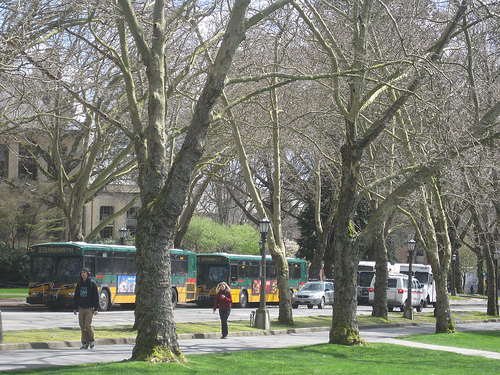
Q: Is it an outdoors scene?
A: Yes, it is outdoors.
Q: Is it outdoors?
A: Yes, it is outdoors.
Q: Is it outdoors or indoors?
A: It is outdoors.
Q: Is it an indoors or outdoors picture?
A: It is outdoors.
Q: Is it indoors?
A: No, it is outdoors.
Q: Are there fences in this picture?
A: No, there are no fences.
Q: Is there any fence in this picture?
A: No, there are no fences.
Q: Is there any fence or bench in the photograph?
A: No, there are no fences or benches.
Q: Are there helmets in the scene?
A: No, there are no helmets.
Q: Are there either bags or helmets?
A: No, there are no helmets or bags.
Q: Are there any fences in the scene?
A: No, there are no fences.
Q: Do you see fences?
A: No, there are no fences.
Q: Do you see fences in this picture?
A: No, there are no fences.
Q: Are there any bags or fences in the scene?
A: No, there are no fences or bags.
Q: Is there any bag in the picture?
A: No, there are no bags.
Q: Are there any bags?
A: No, there are no bags.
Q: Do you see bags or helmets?
A: No, there are no bags or helmets.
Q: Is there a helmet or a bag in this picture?
A: No, there are no bags or helmets.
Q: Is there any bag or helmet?
A: No, there are no bags or helmets.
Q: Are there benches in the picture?
A: No, there are no benches.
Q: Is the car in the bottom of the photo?
A: Yes, the car is in the bottom of the image.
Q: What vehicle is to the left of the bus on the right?
A: The vehicle is a car.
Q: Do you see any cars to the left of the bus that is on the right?
A: Yes, there is a car to the left of the bus.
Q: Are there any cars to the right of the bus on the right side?
A: No, the car is to the left of the bus.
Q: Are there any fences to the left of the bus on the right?
A: No, there is a car to the left of the bus.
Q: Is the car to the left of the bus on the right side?
A: Yes, the car is to the left of the bus.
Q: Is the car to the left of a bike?
A: No, the car is to the left of the bus.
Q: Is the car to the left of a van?
A: Yes, the car is to the left of a van.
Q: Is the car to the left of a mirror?
A: No, the car is to the left of a van.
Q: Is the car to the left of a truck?
A: No, the car is to the left of a van.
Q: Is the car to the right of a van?
A: No, the car is to the left of a van.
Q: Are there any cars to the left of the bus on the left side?
A: No, the car is to the right of the bus.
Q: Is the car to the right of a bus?
A: Yes, the car is to the right of a bus.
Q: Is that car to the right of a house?
A: No, the car is to the right of a bus.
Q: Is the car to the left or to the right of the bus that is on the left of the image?
A: The car is to the right of the bus.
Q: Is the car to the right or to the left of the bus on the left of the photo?
A: The car is to the right of the bus.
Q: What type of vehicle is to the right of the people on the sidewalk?
A: The vehicle is a car.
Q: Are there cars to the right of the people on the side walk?
A: Yes, there is a car to the right of the people.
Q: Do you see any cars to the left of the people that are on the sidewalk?
A: No, the car is to the right of the people.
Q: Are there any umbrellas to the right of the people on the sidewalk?
A: No, there is a car to the right of the people.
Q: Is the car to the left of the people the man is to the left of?
A: No, the car is to the right of the people.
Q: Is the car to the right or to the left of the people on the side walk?
A: The car is to the right of the people.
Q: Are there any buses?
A: Yes, there is a bus.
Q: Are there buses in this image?
A: Yes, there is a bus.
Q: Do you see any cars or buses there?
A: Yes, there is a bus.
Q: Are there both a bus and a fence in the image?
A: No, there is a bus but no fences.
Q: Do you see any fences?
A: No, there are no fences.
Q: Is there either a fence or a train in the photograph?
A: No, there are no fences or trains.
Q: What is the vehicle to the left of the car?
A: The vehicle is a bus.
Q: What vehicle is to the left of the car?
A: The vehicle is a bus.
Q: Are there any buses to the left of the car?
A: Yes, there is a bus to the left of the car.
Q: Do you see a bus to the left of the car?
A: Yes, there is a bus to the left of the car.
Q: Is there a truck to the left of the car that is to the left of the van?
A: No, there is a bus to the left of the car.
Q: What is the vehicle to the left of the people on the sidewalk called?
A: The vehicle is a bus.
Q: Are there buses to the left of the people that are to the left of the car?
A: Yes, there is a bus to the left of the people.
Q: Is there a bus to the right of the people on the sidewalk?
A: No, the bus is to the left of the people.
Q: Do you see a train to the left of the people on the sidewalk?
A: No, there is a bus to the left of the people.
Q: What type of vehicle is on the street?
A: The vehicle is a bus.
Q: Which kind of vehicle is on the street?
A: The vehicle is a bus.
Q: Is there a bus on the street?
A: Yes, there is a bus on the street.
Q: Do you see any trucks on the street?
A: No, there is a bus on the street.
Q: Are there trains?
A: No, there are no trains.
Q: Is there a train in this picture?
A: No, there are no trains.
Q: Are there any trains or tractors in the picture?
A: No, there are no trains or tractors.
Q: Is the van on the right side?
A: Yes, the van is on the right of the image.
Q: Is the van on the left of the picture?
A: No, the van is on the right of the image.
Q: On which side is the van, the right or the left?
A: The van is on the right of the image.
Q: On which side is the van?
A: The van is on the right of the image.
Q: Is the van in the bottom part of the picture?
A: Yes, the van is in the bottom of the image.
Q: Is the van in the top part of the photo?
A: No, the van is in the bottom of the image.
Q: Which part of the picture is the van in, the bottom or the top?
A: The van is in the bottom of the image.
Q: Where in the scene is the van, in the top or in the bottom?
A: The van is in the bottom of the image.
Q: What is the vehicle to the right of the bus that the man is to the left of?
A: The vehicle is a van.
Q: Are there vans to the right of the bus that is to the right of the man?
A: Yes, there is a van to the right of the bus.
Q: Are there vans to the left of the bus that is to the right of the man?
A: No, the van is to the right of the bus.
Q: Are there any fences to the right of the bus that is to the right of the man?
A: No, there is a van to the right of the bus.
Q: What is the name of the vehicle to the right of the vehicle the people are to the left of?
A: The vehicle is a van.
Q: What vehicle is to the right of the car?
A: The vehicle is a van.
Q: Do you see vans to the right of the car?
A: Yes, there is a van to the right of the car.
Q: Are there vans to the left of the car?
A: No, the van is to the right of the car.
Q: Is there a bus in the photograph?
A: Yes, there is a bus.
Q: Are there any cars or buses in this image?
A: Yes, there is a bus.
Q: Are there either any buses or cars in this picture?
A: Yes, there is a bus.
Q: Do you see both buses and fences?
A: No, there is a bus but no fences.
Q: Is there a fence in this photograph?
A: No, there are no fences.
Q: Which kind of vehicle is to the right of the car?
A: The vehicle is a bus.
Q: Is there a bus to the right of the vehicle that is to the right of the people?
A: Yes, there is a bus to the right of the car.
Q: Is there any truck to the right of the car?
A: No, there is a bus to the right of the car.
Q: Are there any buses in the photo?
A: Yes, there is a bus.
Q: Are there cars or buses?
A: Yes, there is a bus.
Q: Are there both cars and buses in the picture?
A: Yes, there are both a bus and a car.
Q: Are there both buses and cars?
A: Yes, there are both a bus and a car.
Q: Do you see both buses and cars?
A: Yes, there are both a bus and a car.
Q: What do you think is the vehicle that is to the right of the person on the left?
A: The vehicle is a bus.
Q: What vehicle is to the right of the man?
A: The vehicle is a bus.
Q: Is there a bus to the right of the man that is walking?
A: Yes, there is a bus to the right of the man.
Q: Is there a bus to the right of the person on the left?
A: Yes, there is a bus to the right of the man.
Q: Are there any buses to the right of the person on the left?
A: Yes, there is a bus to the right of the man.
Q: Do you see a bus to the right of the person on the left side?
A: Yes, there is a bus to the right of the man.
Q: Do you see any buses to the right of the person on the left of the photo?
A: Yes, there is a bus to the right of the man.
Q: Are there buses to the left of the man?
A: No, the bus is to the right of the man.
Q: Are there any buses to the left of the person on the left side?
A: No, the bus is to the right of the man.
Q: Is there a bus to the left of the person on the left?
A: No, the bus is to the right of the man.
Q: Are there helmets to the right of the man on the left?
A: No, there is a bus to the right of the man.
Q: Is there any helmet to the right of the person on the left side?
A: No, there is a bus to the right of the man.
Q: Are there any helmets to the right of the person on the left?
A: No, there is a bus to the right of the man.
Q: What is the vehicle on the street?
A: The vehicle is a bus.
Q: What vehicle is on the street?
A: The vehicle is a bus.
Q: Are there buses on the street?
A: Yes, there is a bus on the street.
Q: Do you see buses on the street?
A: Yes, there is a bus on the street.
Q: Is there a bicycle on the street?
A: No, there is a bus on the street.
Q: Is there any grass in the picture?
A: Yes, there is grass.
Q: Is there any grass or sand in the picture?
A: Yes, there is grass.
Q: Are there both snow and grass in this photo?
A: No, there is grass but no snow.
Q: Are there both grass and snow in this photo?
A: No, there is grass but no snow.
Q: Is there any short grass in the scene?
A: Yes, there is short grass.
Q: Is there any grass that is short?
A: Yes, there is grass that is short.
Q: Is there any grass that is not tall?
A: Yes, there is short grass.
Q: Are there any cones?
A: No, there are no cones.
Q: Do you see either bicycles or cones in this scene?
A: No, there are no cones or bicycles.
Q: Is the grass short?
A: Yes, the grass is short.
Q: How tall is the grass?
A: The grass is short.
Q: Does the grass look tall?
A: No, the grass is short.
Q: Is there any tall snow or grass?
A: No, there is grass but it is short.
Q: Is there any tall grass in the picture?
A: No, there is grass but it is short.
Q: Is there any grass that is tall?
A: No, there is grass but it is short.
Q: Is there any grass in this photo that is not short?
A: No, there is grass but it is short.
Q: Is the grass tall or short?
A: The grass is short.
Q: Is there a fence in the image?
A: No, there are no fences.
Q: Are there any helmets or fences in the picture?
A: No, there are no fences or helmets.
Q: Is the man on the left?
A: Yes, the man is on the left of the image.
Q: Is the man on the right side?
A: No, the man is on the left of the image.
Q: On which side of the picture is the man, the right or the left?
A: The man is on the left of the image.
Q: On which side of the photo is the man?
A: The man is on the left of the image.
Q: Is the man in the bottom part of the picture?
A: Yes, the man is in the bottom of the image.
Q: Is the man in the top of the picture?
A: No, the man is in the bottom of the image.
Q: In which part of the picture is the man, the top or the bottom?
A: The man is in the bottom of the image.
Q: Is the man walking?
A: Yes, the man is walking.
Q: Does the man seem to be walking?
A: Yes, the man is walking.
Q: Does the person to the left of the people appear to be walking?
A: Yes, the man is walking.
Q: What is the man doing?
A: The man is walking.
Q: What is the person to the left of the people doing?
A: The man is walking.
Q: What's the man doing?
A: The man is walking.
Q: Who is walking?
A: The man is walking.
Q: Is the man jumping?
A: No, the man is walking.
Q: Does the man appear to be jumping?
A: No, the man is walking.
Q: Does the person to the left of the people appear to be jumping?
A: No, the man is walking.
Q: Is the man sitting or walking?
A: The man is walking.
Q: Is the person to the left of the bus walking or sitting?
A: The man is walking.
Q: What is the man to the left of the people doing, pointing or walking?
A: The man is walking.